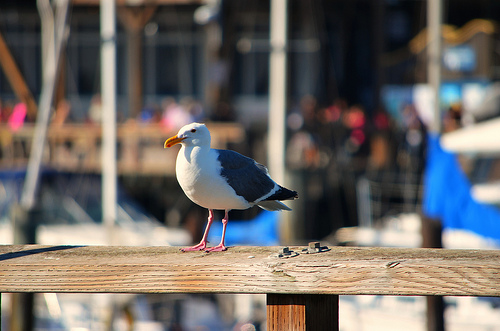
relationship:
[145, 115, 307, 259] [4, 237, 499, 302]
bird on wood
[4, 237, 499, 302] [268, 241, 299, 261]
wood has bolt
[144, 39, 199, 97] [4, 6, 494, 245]
window in back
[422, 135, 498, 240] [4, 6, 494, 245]
material in back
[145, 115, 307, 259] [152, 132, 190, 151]
bird has beak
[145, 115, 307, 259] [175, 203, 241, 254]
bird has legs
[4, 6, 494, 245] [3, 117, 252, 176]
back has support beam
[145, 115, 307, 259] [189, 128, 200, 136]
bird has eye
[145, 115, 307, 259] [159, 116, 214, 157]
bird has head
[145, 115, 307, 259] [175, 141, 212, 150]
bird has neck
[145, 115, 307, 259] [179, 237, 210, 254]
bird has foot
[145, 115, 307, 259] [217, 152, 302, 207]
bird has wing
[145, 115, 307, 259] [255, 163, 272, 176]
bird has feather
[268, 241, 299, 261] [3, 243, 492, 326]
bolt on rail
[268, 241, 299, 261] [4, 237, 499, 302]
bolt in wood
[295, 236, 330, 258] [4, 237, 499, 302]
bolt in wood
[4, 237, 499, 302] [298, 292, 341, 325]
wood has shadow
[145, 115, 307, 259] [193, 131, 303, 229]
bird has shadow